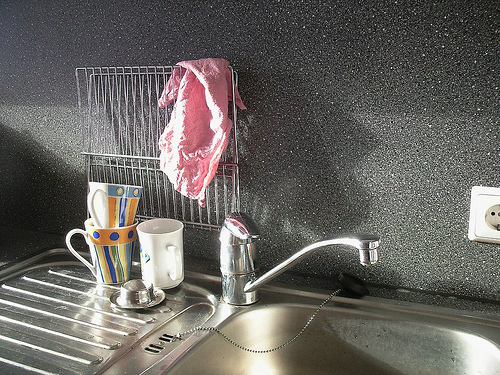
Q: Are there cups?
A: Yes, there is a cup.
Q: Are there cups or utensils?
A: Yes, there is a cup.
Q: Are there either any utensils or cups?
A: Yes, there is a cup.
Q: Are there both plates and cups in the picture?
A: No, there is a cup but no plates.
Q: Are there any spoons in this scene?
A: No, there are no spoons.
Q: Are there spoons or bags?
A: No, there are no spoons or bags.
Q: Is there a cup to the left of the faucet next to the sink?
A: Yes, there is a cup to the left of the tap.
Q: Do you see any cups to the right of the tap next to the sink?
A: No, the cup is to the left of the tap.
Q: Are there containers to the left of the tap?
A: No, there is a cup to the left of the tap.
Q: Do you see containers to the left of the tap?
A: No, there is a cup to the left of the tap.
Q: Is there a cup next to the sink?
A: Yes, there is a cup next to the sink.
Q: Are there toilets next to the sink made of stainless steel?
A: No, there is a cup next to the sink.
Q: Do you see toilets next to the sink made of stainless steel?
A: No, there is a cup next to the sink.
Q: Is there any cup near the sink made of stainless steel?
A: Yes, there is a cup near the sink.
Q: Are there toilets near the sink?
A: No, there is a cup near the sink.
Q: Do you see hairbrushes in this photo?
A: No, there are no hairbrushes.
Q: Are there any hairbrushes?
A: No, there are no hairbrushes.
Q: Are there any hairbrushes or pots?
A: No, there are no hairbrushes or pots.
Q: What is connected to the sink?
A: The chain is connected to the sink.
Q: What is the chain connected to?
A: The chain is connected to the sink.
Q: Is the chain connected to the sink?
A: Yes, the chain is connected to the sink.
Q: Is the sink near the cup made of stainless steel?
A: Yes, the sink is made of stainless steel.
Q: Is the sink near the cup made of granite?
A: No, the sink is made of stainless steel.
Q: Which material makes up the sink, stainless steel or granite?
A: The sink is made of stainless steel.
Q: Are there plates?
A: No, there are no plates.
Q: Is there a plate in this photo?
A: No, there are no plates.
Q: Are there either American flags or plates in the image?
A: No, there are no plates or American flags.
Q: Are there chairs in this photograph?
A: No, there are no chairs.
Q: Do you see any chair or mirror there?
A: No, there are no chairs or mirrors.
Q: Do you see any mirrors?
A: No, there are no mirrors.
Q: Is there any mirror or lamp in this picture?
A: No, there are no mirrors or lamps.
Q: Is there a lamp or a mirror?
A: No, there are no mirrors or lamps.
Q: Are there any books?
A: No, there are no books.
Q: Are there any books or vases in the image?
A: No, there are no books or vases.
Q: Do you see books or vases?
A: No, there are no books or vases.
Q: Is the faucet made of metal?
A: Yes, the faucet is made of metal.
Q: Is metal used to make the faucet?
A: Yes, the faucet is made of metal.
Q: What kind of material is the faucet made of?
A: The faucet is made of metal.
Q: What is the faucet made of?
A: The faucet is made of metal.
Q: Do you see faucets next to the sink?
A: Yes, there is a faucet next to the sink.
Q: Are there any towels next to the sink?
A: No, there is a faucet next to the sink.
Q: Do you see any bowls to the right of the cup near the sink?
A: No, there is a faucet to the right of the cup.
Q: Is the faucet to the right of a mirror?
A: No, the faucet is to the right of the cup.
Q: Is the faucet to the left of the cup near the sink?
A: No, the faucet is to the right of the cup.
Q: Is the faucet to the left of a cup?
A: No, the faucet is to the right of a cup.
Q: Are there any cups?
A: Yes, there is a cup.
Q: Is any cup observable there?
A: Yes, there is a cup.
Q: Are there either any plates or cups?
A: Yes, there is a cup.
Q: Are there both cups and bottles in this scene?
A: No, there is a cup but no bottles.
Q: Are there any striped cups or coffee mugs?
A: Yes, there is a striped cup.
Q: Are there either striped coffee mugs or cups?
A: Yes, there is a striped cup.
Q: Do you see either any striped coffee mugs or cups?
A: Yes, there is a striped cup.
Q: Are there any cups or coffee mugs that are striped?
A: Yes, the cup is striped.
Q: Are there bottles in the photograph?
A: No, there are no bottles.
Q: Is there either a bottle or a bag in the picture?
A: No, there are no bottles or bags.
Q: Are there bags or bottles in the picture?
A: No, there are no bottles or bags.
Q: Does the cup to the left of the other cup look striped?
A: Yes, the cup is striped.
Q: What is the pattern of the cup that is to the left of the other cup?
A: The cup is striped.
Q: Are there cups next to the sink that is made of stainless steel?
A: Yes, there is a cup next to the sink.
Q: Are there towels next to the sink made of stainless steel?
A: No, there is a cup next to the sink.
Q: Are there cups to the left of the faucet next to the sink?
A: Yes, there is a cup to the left of the faucet.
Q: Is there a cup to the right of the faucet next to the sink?
A: No, the cup is to the left of the tap.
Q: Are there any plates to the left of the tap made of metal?
A: No, there is a cup to the left of the faucet.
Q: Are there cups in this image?
A: Yes, there is a cup.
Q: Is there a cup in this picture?
A: Yes, there is a cup.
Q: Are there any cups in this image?
A: Yes, there is a cup.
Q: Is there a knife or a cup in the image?
A: Yes, there is a cup.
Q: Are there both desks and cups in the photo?
A: No, there is a cup but no desks.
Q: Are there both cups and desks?
A: No, there is a cup but no desks.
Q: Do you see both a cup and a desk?
A: No, there is a cup but no desks.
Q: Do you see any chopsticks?
A: No, there are no chopsticks.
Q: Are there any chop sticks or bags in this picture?
A: No, there are no chop sticks or bags.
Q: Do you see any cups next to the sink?
A: Yes, there is a cup next to the sink.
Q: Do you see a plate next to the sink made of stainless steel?
A: No, there is a cup next to the sink.